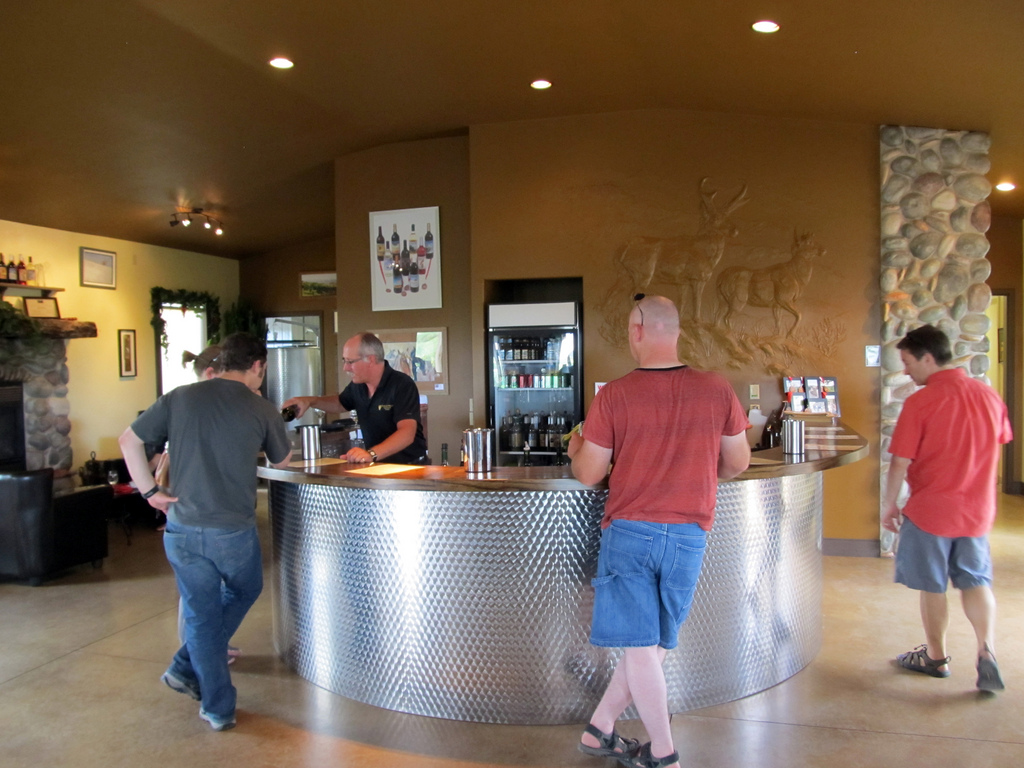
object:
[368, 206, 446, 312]
artwork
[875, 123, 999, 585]
wall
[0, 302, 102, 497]
fireplace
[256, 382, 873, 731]
bar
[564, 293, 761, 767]
man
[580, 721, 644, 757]
sandals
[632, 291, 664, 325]
sunglasses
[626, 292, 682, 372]
head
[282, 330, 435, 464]
bartender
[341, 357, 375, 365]
glasses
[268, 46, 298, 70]
lighting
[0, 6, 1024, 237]
ceiling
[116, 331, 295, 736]
man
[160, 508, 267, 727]
jeans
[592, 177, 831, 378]
deer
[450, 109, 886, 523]
wall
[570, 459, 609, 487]
elbow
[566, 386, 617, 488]
arm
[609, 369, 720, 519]
back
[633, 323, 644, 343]
ear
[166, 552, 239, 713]
legs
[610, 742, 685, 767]
feet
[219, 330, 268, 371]
hair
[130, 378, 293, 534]
shirt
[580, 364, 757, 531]
shirt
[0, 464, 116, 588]
chair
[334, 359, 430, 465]
shirt